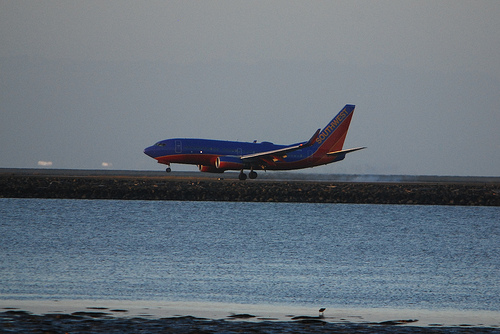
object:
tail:
[309, 104, 356, 150]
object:
[98, 161, 111, 169]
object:
[36, 160, 56, 167]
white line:
[239, 144, 303, 160]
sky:
[0, 0, 499, 177]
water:
[0, 195, 499, 314]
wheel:
[237, 172, 250, 183]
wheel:
[245, 171, 257, 180]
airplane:
[142, 104, 368, 182]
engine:
[211, 153, 251, 172]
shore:
[0, 296, 498, 334]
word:
[312, 106, 352, 146]